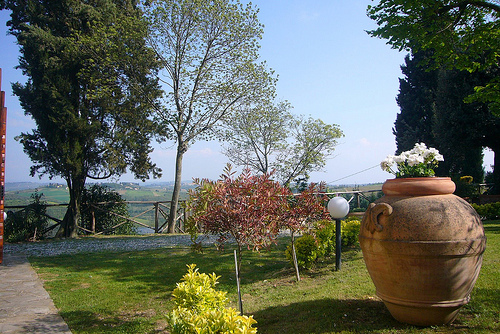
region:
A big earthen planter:
[358, 176, 483, 322]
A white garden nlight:
[326, 195, 348, 220]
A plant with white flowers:
[381, 140, 444, 177]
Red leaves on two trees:
[187, 161, 327, 246]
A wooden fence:
[4, 188, 382, 243]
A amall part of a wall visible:
[1, 67, 8, 262]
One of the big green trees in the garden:
[0, 1, 176, 237]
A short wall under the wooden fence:
[4, 225, 311, 257]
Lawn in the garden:
[25, 219, 497, 332]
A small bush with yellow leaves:
[165, 262, 257, 332]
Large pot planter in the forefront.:
[353, 143, 487, 321]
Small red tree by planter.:
[192, 171, 294, 312]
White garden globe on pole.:
[324, 194, 351, 220]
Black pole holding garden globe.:
[329, 215, 346, 269]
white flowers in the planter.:
[372, 135, 443, 183]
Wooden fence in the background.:
[6, 188, 378, 239]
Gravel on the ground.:
[7, 230, 274, 261]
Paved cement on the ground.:
[0, 253, 69, 332]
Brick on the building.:
[0, 93, 8, 260]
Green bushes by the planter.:
[286, 215, 362, 267]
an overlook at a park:
[37, 23, 457, 309]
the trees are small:
[162, 157, 407, 330]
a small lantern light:
[324, 179, 351, 262]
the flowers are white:
[317, 114, 487, 239]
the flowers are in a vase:
[341, 118, 492, 318]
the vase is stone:
[366, 109, 487, 319]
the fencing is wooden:
[11, 88, 440, 308]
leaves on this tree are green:
[31, 23, 158, 153]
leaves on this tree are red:
[202, 172, 319, 245]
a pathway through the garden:
[6, 205, 173, 330]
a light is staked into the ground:
[321, 178, 351, 281]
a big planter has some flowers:
[358, 138, 480, 317]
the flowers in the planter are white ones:
[376, 140, 443, 177]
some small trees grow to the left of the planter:
[197, 173, 326, 251]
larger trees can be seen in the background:
[23, 13, 494, 199]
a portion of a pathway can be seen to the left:
[3, 251, 60, 332]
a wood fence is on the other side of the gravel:
[2, 192, 382, 231]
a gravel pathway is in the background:
[22, 219, 311, 258]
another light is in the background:
[1, 203, 11, 242]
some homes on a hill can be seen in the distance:
[18, 182, 253, 219]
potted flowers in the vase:
[380, 144, 455, 182]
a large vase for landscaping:
[359, 179, 489, 324]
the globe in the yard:
[326, 194, 351, 271]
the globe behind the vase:
[327, 195, 350, 275]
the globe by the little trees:
[327, 195, 351, 272]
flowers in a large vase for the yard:
[359, 140, 486, 324]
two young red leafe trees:
[195, 178, 330, 318]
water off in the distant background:
[130, 224, 172, 234]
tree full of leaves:
[0, 0, 165, 234]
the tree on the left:
[2, 2, 169, 232]